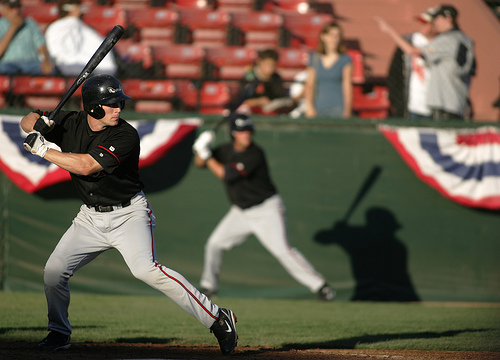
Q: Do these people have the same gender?
A: No, they are both male and female.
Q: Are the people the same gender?
A: No, they are both male and female.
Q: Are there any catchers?
A: No, there are no catchers.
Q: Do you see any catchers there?
A: No, there are no catchers.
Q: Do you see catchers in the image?
A: No, there are no catchers.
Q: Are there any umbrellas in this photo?
A: No, there are no umbrellas.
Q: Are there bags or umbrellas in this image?
A: No, there are no umbrellas or bags.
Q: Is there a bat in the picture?
A: Yes, there is a bat.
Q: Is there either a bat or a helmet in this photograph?
A: Yes, there is a bat.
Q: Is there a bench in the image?
A: No, there are no benches.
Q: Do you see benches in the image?
A: No, there are no benches.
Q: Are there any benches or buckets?
A: No, there are no benches or buckets.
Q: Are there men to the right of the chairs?
A: Yes, there is a man to the right of the chairs.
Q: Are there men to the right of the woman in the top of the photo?
A: Yes, there is a man to the right of the woman.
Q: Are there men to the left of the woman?
A: No, the man is to the right of the woman.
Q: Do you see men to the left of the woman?
A: No, the man is to the right of the woman.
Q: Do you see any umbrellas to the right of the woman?
A: No, there is a man to the right of the woman.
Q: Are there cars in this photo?
A: No, there are no cars.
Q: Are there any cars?
A: No, there are no cars.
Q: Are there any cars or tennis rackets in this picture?
A: No, there are no cars or tennis rackets.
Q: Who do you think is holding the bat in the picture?
A: The man is holding the bat.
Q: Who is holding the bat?
A: The man is holding the bat.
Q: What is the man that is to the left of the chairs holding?
A: The man is holding the bat.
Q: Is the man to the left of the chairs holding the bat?
A: Yes, the man is holding the bat.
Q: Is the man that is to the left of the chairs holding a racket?
A: No, the man is holding the bat.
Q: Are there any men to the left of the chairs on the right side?
A: Yes, there is a man to the left of the chairs.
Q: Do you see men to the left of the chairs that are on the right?
A: Yes, there is a man to the left of the chairs.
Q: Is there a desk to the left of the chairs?
A: No, there is a man to the left of the chairs.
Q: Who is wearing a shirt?
A: The man is wearing a shirt.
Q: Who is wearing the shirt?
A: The man is wearing a shirt.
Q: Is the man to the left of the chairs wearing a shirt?
A: Yes, the man is wearing a shirt.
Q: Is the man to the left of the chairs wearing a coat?
A: No, the man is wearing a shirt.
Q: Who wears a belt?
A: The man wears a belt.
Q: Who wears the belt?
A: The man wears a belt.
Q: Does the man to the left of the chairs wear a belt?
A: Yes, the man wears a belt.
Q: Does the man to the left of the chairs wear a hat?
A: No, the man wears a belt.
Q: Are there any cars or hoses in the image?
A: No, there are no cars or hoses.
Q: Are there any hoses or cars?
A: No, there are no cars or hoses.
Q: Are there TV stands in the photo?
A: No, there are no TV stands.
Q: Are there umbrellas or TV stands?
A: No, there are no TV stands or umbrellas.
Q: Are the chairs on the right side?
A: Yes, the chairs are on the right of the image.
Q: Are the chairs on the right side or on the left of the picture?
A: The chairs are on the right of the image.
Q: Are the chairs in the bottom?
A: No, the chairs are in the top of the image.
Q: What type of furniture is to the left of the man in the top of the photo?
A: The pieces of furniture are chairs.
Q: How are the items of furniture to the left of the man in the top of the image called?
A: The pieces of furniture are chairs.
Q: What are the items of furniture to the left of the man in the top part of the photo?
A: The pieces of furniture are chairs.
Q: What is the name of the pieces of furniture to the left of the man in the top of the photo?
A: The pieces of furniture are chairs.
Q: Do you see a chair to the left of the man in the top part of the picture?
A: Yes, there are chairs to the left of the man.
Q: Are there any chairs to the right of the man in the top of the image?
A: No, the chairs are to the left of the man.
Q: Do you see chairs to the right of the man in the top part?
A: No, the chairs are to the left of the man.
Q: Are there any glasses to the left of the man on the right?
A: No, there are chairs to the left of the man.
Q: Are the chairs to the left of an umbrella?
A: No, the chairs are to the left of the man.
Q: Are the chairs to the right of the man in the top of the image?
A: No, the chairs are to the left of the man.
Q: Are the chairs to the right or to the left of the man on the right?
A: The chairs are to the left of the man.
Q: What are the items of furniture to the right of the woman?
A: The pieces of furniture are chairs.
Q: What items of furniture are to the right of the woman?
A: The pieces of furniture are chairs.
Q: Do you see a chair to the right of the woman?
A: Yes, there are chairs to the right of the woman.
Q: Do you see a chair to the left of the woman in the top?
A: No, the chairs are to the right of the woman.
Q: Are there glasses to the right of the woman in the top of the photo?
A: No, there are chairs to the right of the woman.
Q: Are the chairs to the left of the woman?
A: No, the chairs are to the right of the woman.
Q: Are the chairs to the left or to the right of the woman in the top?
A: The chairs are to the right of the woman.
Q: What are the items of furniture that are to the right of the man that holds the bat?
A: The pieces of furniture are chairs.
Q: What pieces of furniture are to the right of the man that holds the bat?
A: The pieces of furniture are chairs.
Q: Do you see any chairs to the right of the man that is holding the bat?
A: Yes, there are chairs to the right of the man.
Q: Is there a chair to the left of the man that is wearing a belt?
A: No, the chairs are to the right of the man.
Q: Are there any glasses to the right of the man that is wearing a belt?
A: No, there are chairs to the right of the man.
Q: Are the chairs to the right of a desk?
A: No, the chairs are to the right of the man.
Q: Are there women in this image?
A: Yes, there is a woman.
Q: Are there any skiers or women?
A: Yes, there is a woman.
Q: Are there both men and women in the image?
A: Yes, there are both a woman and a man.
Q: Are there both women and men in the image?
A: Yes, there are both a woman and a man.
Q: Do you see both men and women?
A: Yes, there are both a woman and a man.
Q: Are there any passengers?
A: No, there are no passengers.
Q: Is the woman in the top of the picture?
A: Yes, the woman is in the top of the image.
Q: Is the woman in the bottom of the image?
A: No, the woman is in the top of the image.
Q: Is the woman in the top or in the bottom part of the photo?
A: The woman is in the top of the image.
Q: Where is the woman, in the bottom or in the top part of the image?
A: The woman is in the top of the image.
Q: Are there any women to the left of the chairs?
A: Yes, there is a woman to the left of the chairs.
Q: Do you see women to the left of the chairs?
A: Yes, there is a woman to the left of the chairs.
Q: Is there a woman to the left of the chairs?
A: Yes, there is a woman to the left of the chairs.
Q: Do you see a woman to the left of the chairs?
A: Yes, there is a woman to the left of the chairs.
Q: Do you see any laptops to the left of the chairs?
A: No, there is a woman to the left of the chairs.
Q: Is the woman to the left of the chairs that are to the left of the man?
A: Yes, the woman is to the left of the chairs.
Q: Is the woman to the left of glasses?
A: No, the woman is to the left of the chairs.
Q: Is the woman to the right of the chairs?
A: No, the woman is to the left of the chairs.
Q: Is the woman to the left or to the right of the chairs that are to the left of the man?
A: The woman is to the left of the chairs.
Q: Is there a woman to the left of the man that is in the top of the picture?
A: Yes, there is a woman to the left of the man.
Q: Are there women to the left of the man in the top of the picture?
A: Yes, there is a woman to the left of the man.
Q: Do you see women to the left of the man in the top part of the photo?
A: Yes, there is a woman to the left of the man.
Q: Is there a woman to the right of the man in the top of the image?
A: No, the woman is to the left of the man.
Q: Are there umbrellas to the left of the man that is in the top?
A: No, there is a woman to the left of the man.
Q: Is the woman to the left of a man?
A: Yes, the woman is to the left of a man.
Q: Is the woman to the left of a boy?
A: No, the woman is to the left of a man.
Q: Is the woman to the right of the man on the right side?
A: No, the woman is to the left of the man.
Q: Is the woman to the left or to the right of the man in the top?
A: The woman is to the left of the man.